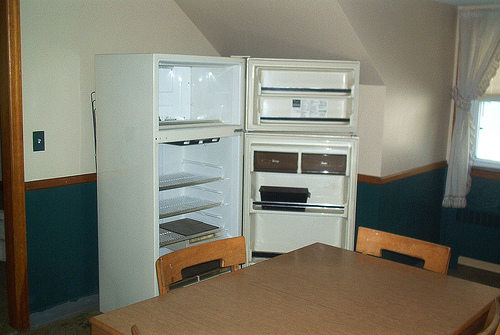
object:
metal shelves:
[158, 176, 220, 192]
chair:
[153, 234, 248, 296]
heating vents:
[452, 204, 499, 230]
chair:
[353, 226, 451, 281]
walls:
[25, 2, 498, 312]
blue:
[41, 194, 61, 208]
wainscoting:
[24, 181, 101, 313]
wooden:
[355, 173, 381, 187]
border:
[378, 159, 446, 185]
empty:
[158, 175, 223, 218]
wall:
[23, 0, 225, 316]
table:
[89, 242, 500, 334]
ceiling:
[173, 0, 388, 86]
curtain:
[437, 3, 499, 209]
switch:
[29, 131, 51, 153]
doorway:
[0, 0, 27, 334]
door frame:
[0, 1, 30, 334]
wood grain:
[466, 166, 499, 181]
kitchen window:
[472, 99, 498, 163]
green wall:
[23, 172, 101, 317]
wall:
[336, 0, 460, 266]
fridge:
[93, 51, 361, 314]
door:
[244, 55, 361, 133]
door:
[239, 135, 359, 267]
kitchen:
[0, 0, 496, 333]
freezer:
[156, 59, 248, 135]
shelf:
[158, 162, 224, 191]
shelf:
[154, 193, 222, 221]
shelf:
[157, 218, 222, 249]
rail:
[24, 172, 98, 194]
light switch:
[36, 136, 42, 146]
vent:
[451, 207, 499, 231]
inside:
[158, 61, 238, 125]